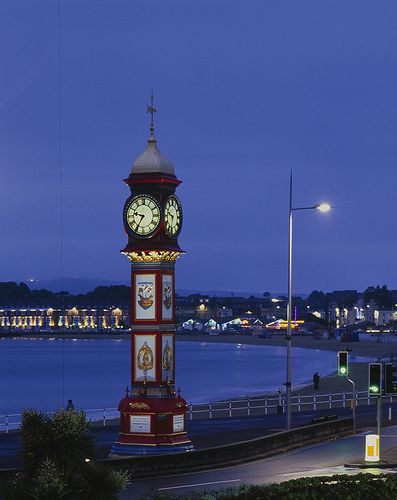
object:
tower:
[108, 87, 207, 455]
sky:
[2, 5, 396, 294]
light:
[279, 151, 330, 427]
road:
[14, 390, 396, 484]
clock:
[123, 191, 162, 237]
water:
[2, 328, 308, 420]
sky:
[141, 53, 304, 131]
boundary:
[87, 418, 356, 480]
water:
[0, 334, 369, 414]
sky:
[248, 25, 294, 83]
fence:
[0, 388, 396, 433]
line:
[154, 475, 241, 486]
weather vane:
[144, 91, 158, 143]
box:
[362, 432, 380, 463]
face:
[125, 191, 159, 235]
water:
[3, 332, 327, 425]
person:
[62, 397, 77, 410]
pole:
[292, 304, 300, 326]